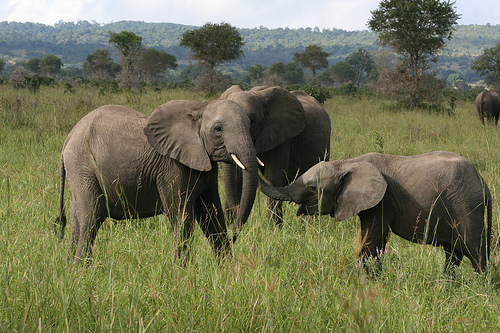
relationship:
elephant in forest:
[50, 98, 264, 269] [1, 1, 499, 98]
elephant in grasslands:
[50, 98, 264, 269] [1, 80, 499, 330]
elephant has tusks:
[56, 98, 264, 260] [231, 153, 265, 169]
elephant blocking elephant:
[56, 98, 264, 260] [219, 86, 331, 241]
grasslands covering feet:
[1, 80, 499, 330] [69, 219, 494, 281]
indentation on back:
[85, 102, 102, 172] [76, 103, 148, 143]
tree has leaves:
[366, 1, 462, 120] [366, 0, 461, 61]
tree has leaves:
[181, 20, 241, 96] [178, 22, 247, 65]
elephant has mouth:
[251, 150, 493, 272] [290, 197, 306, 216]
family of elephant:
[56, 84, 490, 280] [50, 98, 264, 269]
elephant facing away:
[475, 89, 499, 126] [475, 89, 498, 124]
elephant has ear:
[56, 98, 264, 260] [148, 99, 213, 171]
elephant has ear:
[219, 86, 331, 241] [254, 88, 306, 152]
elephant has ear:
[251, 150, 493, 272] [335, 161, 389, 222]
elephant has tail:
[56, 98, 264, 260] [55, 133, 71, 254]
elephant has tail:
[251, 150, 493, 272] [482, 181, 492, 262]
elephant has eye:
[56, 98, 264, 260] [212, 123, 223, 133]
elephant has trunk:
[251, 150, 493, 272] [256, 176, 301, 202]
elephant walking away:
[475, 89, 499, 126] [475, 89, 498, 124]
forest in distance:
[1, 1, 499, 98] [1, 2, 498, 101]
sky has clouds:
[1, 1, 499, 30] [11, 1, 79, 23]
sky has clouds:
[1, 1, 499, 30] [310, 3, 354, 31]